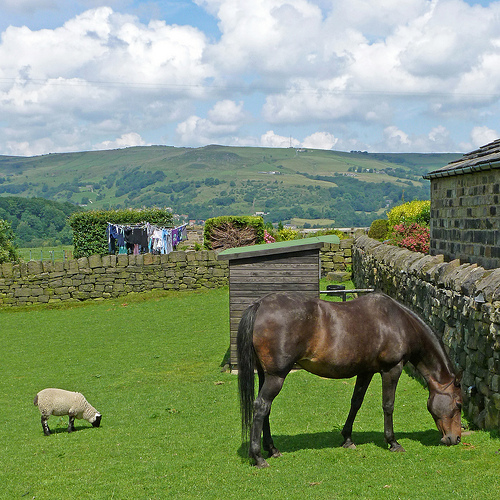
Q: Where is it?
A: This is at the field.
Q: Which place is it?
A: It is a field.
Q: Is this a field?
A: Yes, it is a field.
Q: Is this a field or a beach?
A: It is a field.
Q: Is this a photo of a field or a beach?
A: It is showing a field.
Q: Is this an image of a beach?
A: No, the picture is showing a field.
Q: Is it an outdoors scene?
A: Yes, it is outdoors.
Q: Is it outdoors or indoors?
A: It is outdoors.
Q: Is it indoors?
A: No, it is outdoors.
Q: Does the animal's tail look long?
A: Yes, the tail is long.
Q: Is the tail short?
A: No, the tail is long.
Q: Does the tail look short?
A: No, the tail is long.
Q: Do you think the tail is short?
A: No, the tail is long.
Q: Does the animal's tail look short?
A: No, the tail is long.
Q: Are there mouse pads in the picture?
A: No, there are no mouse pads.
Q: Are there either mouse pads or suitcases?
A: No, there are no mouse pads or suitcases.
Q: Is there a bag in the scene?
A: No, there are no bags.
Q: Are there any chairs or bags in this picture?
A: No, there are no bags or chairs.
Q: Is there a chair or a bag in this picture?
A: No, there are no bags or chairs.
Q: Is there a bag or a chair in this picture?
A: No, there are no bags or chairs.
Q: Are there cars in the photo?
A: No, there are no cars.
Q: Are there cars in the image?
A: No, there are no cars.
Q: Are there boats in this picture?
A: No, there are no boats.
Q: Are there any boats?
A: No, there are no boats.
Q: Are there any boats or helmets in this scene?
A: No, there are no boats or helmets.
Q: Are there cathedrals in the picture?
A: No, there are no cathedrals.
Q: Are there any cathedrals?
A: No, there are no cathedrals.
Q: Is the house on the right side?
A: Yes, the house is on the right of the image.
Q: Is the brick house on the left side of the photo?
A: No, the house is on the right of the image.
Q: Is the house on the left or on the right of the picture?
A: The house is on the right of the image.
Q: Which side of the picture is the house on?
A: The house is on the right of the image.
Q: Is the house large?
A: Yes, the house is large.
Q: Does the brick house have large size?
A: Yes, the house is large.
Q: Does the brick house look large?
A: Yes, the house is large.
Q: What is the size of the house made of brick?
A: The house is large.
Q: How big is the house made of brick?
A: The house is large.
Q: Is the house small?
A: No, the house is large.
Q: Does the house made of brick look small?
A: No, the house is large.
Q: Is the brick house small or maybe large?
A: The house is large.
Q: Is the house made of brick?
A: Yes, the house is made of brick.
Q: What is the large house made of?
A: The house is made of brick.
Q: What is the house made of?
A: The house is made of brick.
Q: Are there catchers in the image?
A: No, there are no catchers.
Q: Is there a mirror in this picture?
A: No, there are no mirrors.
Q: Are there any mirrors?
A: No, there are no mirrors.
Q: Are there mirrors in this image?
A: No, there are no mirrors.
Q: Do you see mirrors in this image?
A: No, there are no mirrors.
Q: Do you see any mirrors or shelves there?
A: No, there are no mirrors or shelves.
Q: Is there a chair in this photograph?
A: No, there are no chairs.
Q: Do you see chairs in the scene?
A: No, there are no chairs.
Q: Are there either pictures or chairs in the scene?
A: No, there are no chairs or pictures.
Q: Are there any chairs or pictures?
A: No, there are no chairs or pictures.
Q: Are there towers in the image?
A: No, there are no towers.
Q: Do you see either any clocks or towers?
A: No, there are no towers or clocks.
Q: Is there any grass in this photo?
A: Yes, there is grass.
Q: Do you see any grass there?
A: Yes, there is grass.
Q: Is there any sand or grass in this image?
A: Yes, there is grass.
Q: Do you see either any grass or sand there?
A: Yes, there is grass.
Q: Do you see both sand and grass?
A: No, there is grass but no sand.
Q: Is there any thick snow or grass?
A: Yes, there is thick grass.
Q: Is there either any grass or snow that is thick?
A: Yes, the grass is thick.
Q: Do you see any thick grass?
A: Yes, there is thick grass.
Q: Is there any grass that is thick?
A: Yes, there is grass that is thick.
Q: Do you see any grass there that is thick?
A: Yes, there is grass that is thick.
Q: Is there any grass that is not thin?
A: Yes, there is thick grass.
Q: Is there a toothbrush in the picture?
A: No, there are no toothbrushes.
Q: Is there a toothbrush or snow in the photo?
A: No, there are no toothbrushes or snow.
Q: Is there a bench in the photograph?
A: No, there are no benches.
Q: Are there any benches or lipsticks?
A: No, there are no benches or lipsticks.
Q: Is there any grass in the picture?
A: Yes, there is grass.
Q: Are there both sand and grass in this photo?
A: No, there is grass but no sand.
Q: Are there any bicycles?
A: No, there are no bicycles.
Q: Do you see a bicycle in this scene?
A: No, there are no bicycles.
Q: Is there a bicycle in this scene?
A: No, there are no bicycles.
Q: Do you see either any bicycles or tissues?
A: No, there are no bicycles or tissues.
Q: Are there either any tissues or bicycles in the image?
A: No, there are no bicycles or tissues.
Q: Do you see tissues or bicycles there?
A: No, there are no bicycles or tissues.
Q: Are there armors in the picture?
A: No, there are no armors.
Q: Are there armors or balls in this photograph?
A: No, there are no armors or balls.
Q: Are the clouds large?
A: Yes, the clouds are large.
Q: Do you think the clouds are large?
A: Yes, the clouds are large.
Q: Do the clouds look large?
A: Yes, the clouds are large.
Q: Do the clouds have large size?
A: Yes, the clouds are large.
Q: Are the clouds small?
A: No, the clouds are large.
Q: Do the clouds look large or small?
A: The clouds are large.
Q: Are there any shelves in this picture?
A: No, there are no shelves.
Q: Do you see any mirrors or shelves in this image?
A: No, there are no shelves or mirrors.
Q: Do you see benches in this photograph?
A: No, there are no benches.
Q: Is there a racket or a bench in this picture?
A: No, there are no benches or rackets.